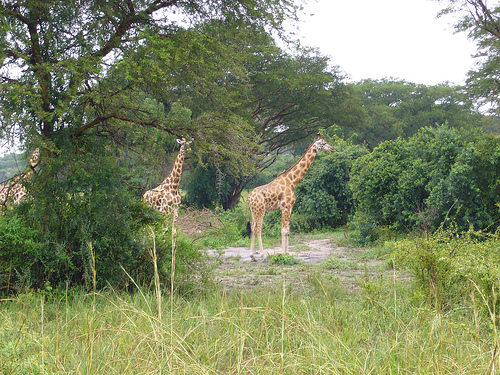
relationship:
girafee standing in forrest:
[239, 133, 338, 271] [16, 29, 482, 293]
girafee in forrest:
[239, 133, 338, 271] [16, 29, 482, 293]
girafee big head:
[239, 133, 338, 271] [314, 137, 341, 155]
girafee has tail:
[239, 133, 338, 271] [244, 200, 257, 231]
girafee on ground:
[239, 133, 338, 271] [231, 252, 287, 283]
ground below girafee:
[231, 252, 287, 283] [239, 133, 338, 271]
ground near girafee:
[231, 252, 287, 283] [239, 133, 338, 271]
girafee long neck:
[239, 133, 338, 271] [293, 154, 319, 179]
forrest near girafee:
[16, 29, 482, 293] [239, 133, 338, 271]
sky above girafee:
[343, 3, 409, 44] [239, 133, 338, 271]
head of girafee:
[314, 137, 341, 155] [239, 133, 338, 271]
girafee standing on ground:
[239, 133, 338, 271] [231, 252, 287, 283]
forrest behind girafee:
[16, 29, 482, 293] [239, 133, 338, 271]